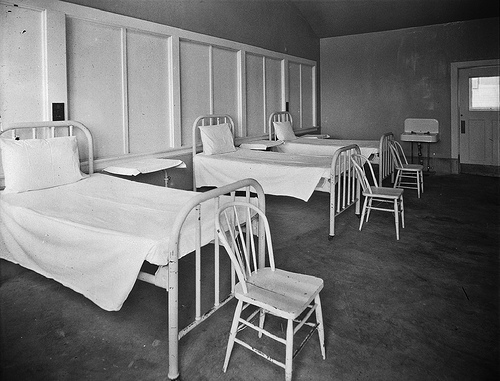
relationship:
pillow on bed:
[1, 132, 81, 187] [268, 109, 396, 186]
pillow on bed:
[0, 135, 90, 195] [1, 170, 260, 300]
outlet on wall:
[45, 92, 72, 137] [0, 64, 76, 149]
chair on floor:
[215, 202, 327, 381] [22, 175, 492, 375]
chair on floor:
[350, 153, 405, 241] [411, 249, 442, 305]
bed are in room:
[192, 114, 361, 241] [11, 64, 400, 318]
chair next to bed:
[215, 202, 327, 381] [2, 119, 269, 379]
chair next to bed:
[343, 148, 410, 238] [190, 113, 368, 239]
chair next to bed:
[384, 138, 427, 201] [264, 104, 401, 186]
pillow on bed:
[195, 122, 247, 157] [188, 139, 396, 211]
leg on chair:
[279, 317, 299, 378] [215, 202, 327, 381]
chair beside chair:
[350, 153, 405, 241] [379, 138, 429, 198]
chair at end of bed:
[215, 202, 327, 381] [2, 119, 269, 379]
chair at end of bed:
[350, 153, 405, 241] [190, 113, 368, 239]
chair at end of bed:
[388, 140, 425, 198] [268, 109, 396, 186]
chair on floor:
[350, 153, 405, 241] [22, 175, 492, 375]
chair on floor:
[388, 140, 425, 198] [22, 175, 492, 375]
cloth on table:
[85, 148, 186, 178] [107, 127, 199, 191]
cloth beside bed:
[235, 135, 281, 151] [190, 113, 368, 239]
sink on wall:
[399, 114, 444, 148] [314, 15, 498, 177]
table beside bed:
[107, 152, 190, 179] [2, 119, 269, 379]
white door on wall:
[459, 69, 500, 167] [314, 15, 498, 177]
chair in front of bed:
[215, 202, 327, 381] [18, 174, 220, 314]